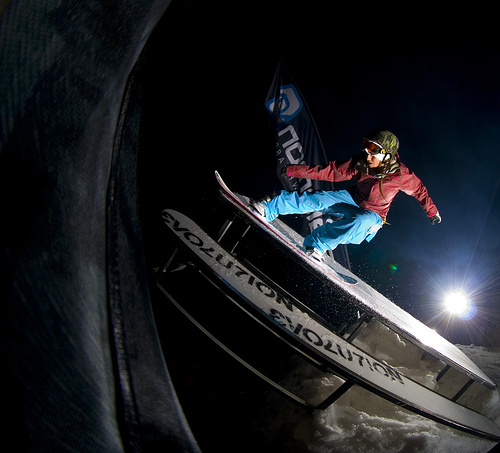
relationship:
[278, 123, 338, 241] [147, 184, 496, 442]
letters on wall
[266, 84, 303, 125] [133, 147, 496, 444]
logo on wall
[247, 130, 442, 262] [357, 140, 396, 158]
he has goggles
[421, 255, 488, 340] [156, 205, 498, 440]
light behind bench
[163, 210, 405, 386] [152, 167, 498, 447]
writing on bench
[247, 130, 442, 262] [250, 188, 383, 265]
he wearing pants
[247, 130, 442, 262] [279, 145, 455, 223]
he wearing jacket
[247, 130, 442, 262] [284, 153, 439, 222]
he wearing jacket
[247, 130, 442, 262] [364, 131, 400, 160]
he wearing hat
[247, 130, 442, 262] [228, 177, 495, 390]
he using snowboard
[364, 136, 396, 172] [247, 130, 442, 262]
head of he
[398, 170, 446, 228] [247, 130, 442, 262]
arm of he